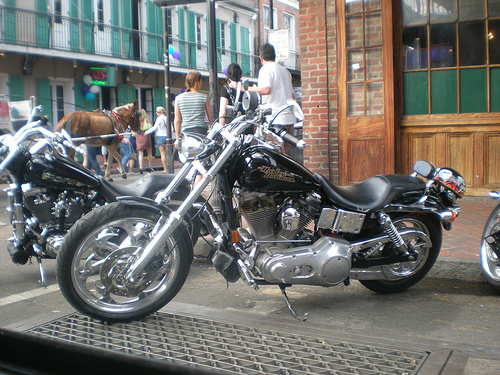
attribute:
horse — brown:
[54, 98, 149, 181]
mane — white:
[106, 102, 141, 114]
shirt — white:
[254, 61, 299, 126]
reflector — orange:
[224, 222, 250, 246]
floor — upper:
[51, 42, 168, 68]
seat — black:
[312, 171, 424, 208]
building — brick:
[290, 2, 497, 199]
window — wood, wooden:
[389, 6, 499, 121]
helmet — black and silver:
[426, 165, 463, 200]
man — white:
[249, 41, 294, 112]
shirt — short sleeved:
[259, 59, 293, 107]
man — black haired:
[247, 29, 298, 153]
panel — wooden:
[406, 127, 438, 173]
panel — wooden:
[441, 127, 474, 188]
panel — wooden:
[482, 127, 499, 190]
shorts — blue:
[146, 127, 179, 152]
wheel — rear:
[350, 197, 442, 294]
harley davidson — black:
[55, 80, 467, 325]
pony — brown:
[54, 90, 222, 195]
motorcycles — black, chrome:
[176, 121, 395, 236]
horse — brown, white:
[67, 94, 154, 150]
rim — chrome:
[78, 225, 169, 304]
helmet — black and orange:
[428, 162, 468, 204]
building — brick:
[285, 5, 448, 215]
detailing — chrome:
[174, 102, 389, 294]